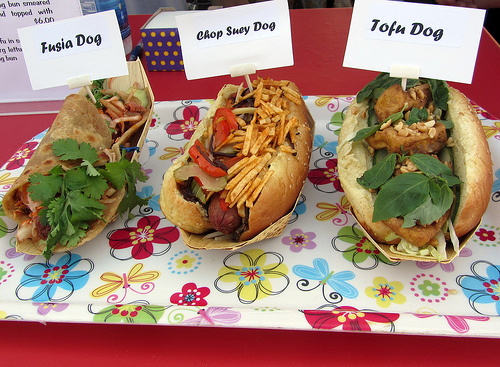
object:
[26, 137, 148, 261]
cilantro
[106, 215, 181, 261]
flower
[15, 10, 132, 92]
sign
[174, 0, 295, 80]
sign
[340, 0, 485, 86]
sign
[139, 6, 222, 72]
box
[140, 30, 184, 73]
dots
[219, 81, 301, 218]
potatoes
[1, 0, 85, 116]
menu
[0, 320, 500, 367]
ground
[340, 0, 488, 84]
white sign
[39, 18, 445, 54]
letters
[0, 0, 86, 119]
sign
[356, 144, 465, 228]
basil leaves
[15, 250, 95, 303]
flowers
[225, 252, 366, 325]
cloth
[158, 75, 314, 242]
bread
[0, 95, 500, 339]
board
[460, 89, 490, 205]
sesame seeds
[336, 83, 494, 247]
bun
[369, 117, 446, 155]
marinated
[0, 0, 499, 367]
serving table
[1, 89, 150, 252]
bun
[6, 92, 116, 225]
tortilla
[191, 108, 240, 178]
tomatoes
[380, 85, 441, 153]
tofu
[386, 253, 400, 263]
part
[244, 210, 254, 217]
part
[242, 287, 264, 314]
part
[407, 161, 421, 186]
part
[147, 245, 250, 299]
part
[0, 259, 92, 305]
part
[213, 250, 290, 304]
flower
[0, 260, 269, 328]
table cloth